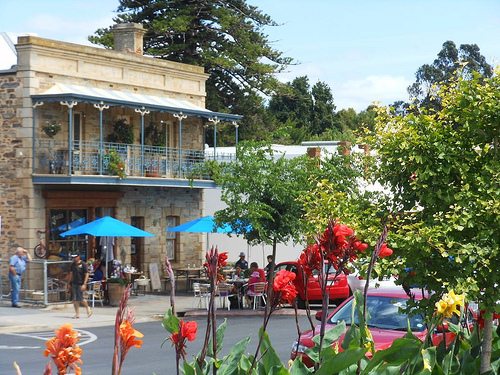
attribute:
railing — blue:
[35, 138, 242, 178]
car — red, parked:
[334, 287, 436, 370]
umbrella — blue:
[80, 209, 143, 250]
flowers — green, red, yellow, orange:
[310, 220, 388, 326]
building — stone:
[80, 74, 212, 181]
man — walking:
[62, 252, 98, 306]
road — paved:
[187, 328, 251, 356]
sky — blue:
[328, 18, 379, 54]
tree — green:
[425, 57, 475, 132]